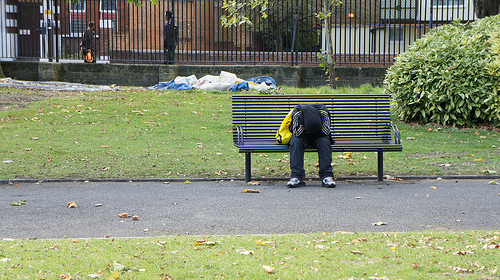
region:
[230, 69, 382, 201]
the person is sitting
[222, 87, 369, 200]
person sitting on the bench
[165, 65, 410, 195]
the bench is black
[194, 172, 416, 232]
the ground is grey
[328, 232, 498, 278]
leaves on the grass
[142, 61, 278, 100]
garbage in the background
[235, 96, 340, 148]
person is wearing a hood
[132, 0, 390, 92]
a fence in the background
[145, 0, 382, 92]
the fence is black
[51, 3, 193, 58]
people in the background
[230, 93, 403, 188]
the bench with someone sitting on it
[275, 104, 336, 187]
the person sitting on the bench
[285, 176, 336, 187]
the shoes on the person's feet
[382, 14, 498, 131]
the large bush near the bench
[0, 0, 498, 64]
the metal gate behind the bench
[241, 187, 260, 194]
the leaf on the ground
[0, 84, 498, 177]
the grass behind the bench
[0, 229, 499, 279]
the grass area in front of the bench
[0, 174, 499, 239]
the walkway between the grassy areas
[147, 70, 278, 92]
the pile of stuff behind the bench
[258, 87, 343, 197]
a person sitting the bench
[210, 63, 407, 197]
a person sitting the bench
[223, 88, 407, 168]
the bench is black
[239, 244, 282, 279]
Brown leaves covering the ground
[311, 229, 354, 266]
Brown leaves covering the ground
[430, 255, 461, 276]
Brown leaves covering the ground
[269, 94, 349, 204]
Man sitting on a bench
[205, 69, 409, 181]
Large wooden bench on pavement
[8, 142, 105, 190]
Brown leaves covering the ground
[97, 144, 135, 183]
Brown leaves covering the ground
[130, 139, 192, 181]
Brown leaves covering the ground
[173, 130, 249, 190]
Brown leaves covering the ground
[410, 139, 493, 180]
Brown leaves covering the ground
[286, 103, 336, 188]
person sitting on a park bench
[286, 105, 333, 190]
person bent over on a park bench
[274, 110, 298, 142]
yellow bag next to the person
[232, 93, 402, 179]
black metal park bench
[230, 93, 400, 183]
black bench with a person on it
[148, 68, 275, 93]
pile of trash in the field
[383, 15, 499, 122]
bushes growing in the field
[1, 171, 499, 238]
concrete path in the park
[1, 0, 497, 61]
black metal fence around the park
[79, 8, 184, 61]
people walking behind the fence